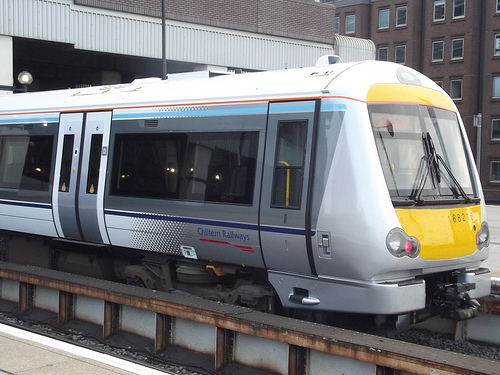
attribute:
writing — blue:
[197, 225, 249, 242]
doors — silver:
[48, 105, 113, 247]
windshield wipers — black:
[411, 131, 470, 204]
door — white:
[50, 107, 115, 252]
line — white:
[0, 322, 161, 373]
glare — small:
[163, 165, 181, 174]